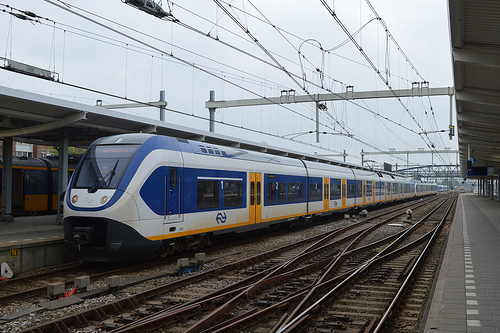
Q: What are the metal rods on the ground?
A: Rails.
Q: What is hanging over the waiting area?
A: Eves.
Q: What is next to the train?
A: Tracks.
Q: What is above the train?
A: Electrical equipment.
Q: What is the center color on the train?
A: Blue.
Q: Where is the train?
A: At the station.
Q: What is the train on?
A: Tracks.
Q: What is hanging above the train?
A: Wires.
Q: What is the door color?
A: Yellow.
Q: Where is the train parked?
A: At the station.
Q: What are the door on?
A: The cars.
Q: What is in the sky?
A: It's clouds.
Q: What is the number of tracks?
A: It's three.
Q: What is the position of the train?
A: It's stopped.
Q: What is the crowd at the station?
A: It's empty.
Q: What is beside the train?
A: A train.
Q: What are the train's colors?
A: It's white, blue, and yellow.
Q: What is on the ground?
A: It's train tracks.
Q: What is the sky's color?
A: It's gray.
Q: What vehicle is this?
A: Train.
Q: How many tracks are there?
A: Three.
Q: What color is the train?
A: White and blue.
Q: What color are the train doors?
A: Yellow.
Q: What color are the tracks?
A: Brown.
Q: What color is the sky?
A: White.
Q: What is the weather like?
A: Cloudy.